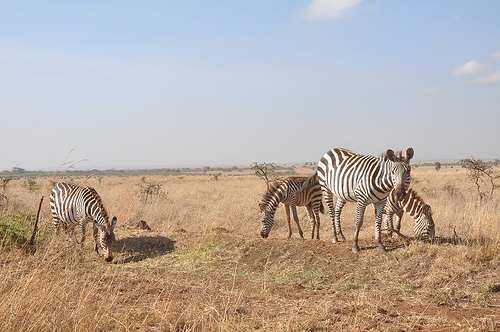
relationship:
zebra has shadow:
[52, 182, 121, 260] [102, 221, 173, 275]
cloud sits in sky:
[429, 42, 492, 107] [112, 22, 357, 76]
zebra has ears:
[52, 182, 121, 260] [89, 220, 118, 235]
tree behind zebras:
[252, 156, 287, 202] [242, 140, 444, 255]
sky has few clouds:
[112, 22, 357, 76] [320, 5, 491, 99]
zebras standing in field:
[242, 140, 444, 255] [101, 186, 348, 319]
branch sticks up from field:
[18, 195, 53, 252] [0, 186, 500, 331]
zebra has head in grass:
[52, 182, 121, 260] [38, 274, 269, 324]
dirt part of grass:
[102, 273, 201, 331] [38, 274, 269, 324]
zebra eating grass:
[52, 182, 121, 260] [38, 274, 269, 324]